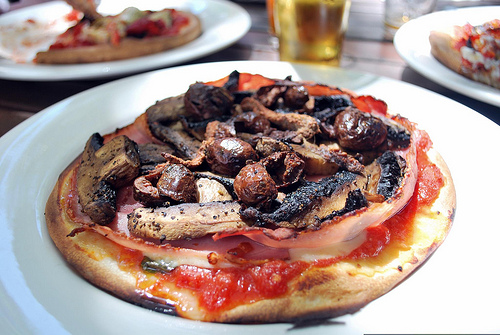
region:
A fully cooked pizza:
[40, 67, 471, 330]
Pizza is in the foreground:
[27, 60, 466, 330]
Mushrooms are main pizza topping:
[61, 70, 422, 254]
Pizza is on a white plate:
[3, 61, 498, 333]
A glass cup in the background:
[270, 0, 348, 70]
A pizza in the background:
[0, 0, 256, 83]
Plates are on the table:
[0, 10, 499, 136]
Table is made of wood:
[0, 9, 499, 139]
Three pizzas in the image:
[0, 0, 498, 324]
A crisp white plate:
[15, 273, 82, 329]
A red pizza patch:
[195, 260, 347, 304]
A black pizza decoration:
[286, 177, 327, 218]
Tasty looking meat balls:
[205, 137, 281, 206]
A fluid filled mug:
[260, 1, 358, 59]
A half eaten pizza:
[31, 6, 206, 69]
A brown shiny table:
[371, 45, 391, 71]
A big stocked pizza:
[45, 68, 455, 329]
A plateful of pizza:
[431, 17, 498, 82]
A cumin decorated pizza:
[125, 192, 240, 240]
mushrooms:
[140, 200, 225, 242]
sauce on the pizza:
[211, 268, 281, 305]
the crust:
[92, 240, 132, 286]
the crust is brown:
[75, 238, 114, 283]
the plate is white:
[29, 253, 79, 311]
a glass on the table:
[267, 5, 342, 55]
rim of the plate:
[85, 55, 125, 75]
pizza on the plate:
[430, 27, 498, 59]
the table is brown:
[360, 30, 395, 74]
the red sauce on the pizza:
[420, 160, 439, 206]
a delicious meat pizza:
[44, 71, 457, 323]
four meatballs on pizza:
[156, 106, 390, 204]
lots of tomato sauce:
[150, 73, 445, 329]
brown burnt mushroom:
[73, 128, 140, 227]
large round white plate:
[0, 59, 499, 333]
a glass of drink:
[271, 0, 350, 62]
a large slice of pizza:
[26, 7, 202, 67]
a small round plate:
[0, 0, 255, 82]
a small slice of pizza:
[428, 18, 498, 85]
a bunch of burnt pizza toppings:
[73, 71, 413, 245]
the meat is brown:
[142, 106, 348, 190]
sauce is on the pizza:
[145, 254, 317, 321]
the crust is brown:
[53, 239, 138, 306]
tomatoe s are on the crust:
[177, 254, 289, 301]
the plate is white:
[8, 141, 40, 317]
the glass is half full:
[276, 4, 364, 72]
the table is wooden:
[357, 16, 394, 88]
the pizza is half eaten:
[42, 15, 204, 60]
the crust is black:
[297, 176, 355, 191]